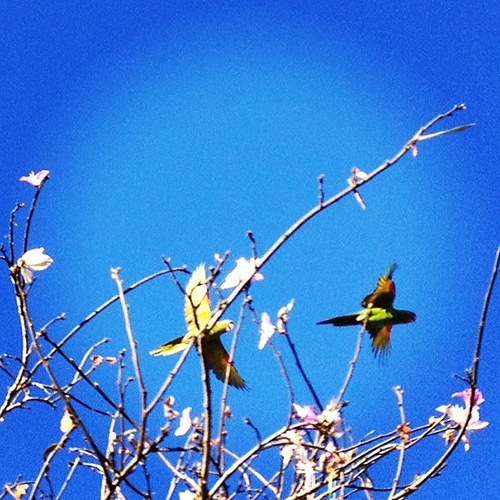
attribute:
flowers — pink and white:
[6, 224, 494, 497]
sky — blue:
[1, 2, 498, 499]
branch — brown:
[169, 91, 476, 369]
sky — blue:
[83, 25, 290, 162]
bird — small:
[311, 270, 422, 372]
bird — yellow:
[316, 272, 416, 369]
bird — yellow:
[147, 263, 249, 389]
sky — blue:
[7, 12, 490, 244]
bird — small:
[145, 259, 250, 395]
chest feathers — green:
[355, 305, 395, 329]